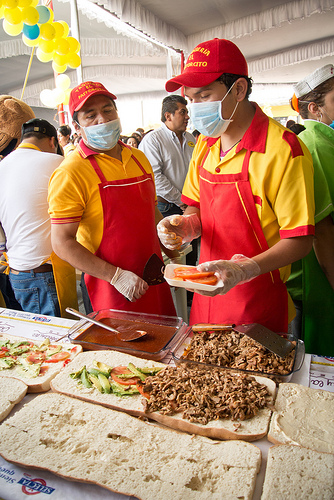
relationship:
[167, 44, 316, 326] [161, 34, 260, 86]
man wearing hat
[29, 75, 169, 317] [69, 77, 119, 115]
man wearing hat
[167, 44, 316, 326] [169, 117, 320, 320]
man wearing shirt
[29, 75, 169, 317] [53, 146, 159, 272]
man wearing shirt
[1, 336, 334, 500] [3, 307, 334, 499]
bread on table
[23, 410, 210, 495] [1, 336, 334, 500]
guacamole on bread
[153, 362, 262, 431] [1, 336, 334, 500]
meat on bread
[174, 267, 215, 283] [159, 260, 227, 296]
tomatoes in a tray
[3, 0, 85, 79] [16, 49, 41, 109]
balloons on a stick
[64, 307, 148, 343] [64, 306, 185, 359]
spoon in baking dish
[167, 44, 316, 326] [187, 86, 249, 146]
man wearing mask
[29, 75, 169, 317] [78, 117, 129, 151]
man wearing mask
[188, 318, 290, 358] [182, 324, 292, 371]
spatula on top of meat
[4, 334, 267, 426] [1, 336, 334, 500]
food on bread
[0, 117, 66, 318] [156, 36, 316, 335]
person behind man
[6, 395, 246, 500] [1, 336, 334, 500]
slice of bread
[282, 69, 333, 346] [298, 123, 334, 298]
woman in shirt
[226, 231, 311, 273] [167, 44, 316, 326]
arm of man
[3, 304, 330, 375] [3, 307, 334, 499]
edge of table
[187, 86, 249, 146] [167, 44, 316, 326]
face of man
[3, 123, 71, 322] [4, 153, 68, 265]
back of person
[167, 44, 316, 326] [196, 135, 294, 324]
man wearing apron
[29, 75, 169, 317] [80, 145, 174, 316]
man wearing apron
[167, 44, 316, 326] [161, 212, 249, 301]
man wearing gloves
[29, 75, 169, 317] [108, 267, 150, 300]
man wearing gloves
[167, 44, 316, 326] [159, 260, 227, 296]
man holding tray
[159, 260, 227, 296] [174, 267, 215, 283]
tray of tomatoes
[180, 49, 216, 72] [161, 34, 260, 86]
lettering on hat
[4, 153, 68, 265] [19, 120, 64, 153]
person wearing hat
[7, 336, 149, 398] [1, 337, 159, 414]
vegetables on slices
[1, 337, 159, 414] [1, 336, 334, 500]
slices of bread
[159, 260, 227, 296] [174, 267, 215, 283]
tray with tomatoes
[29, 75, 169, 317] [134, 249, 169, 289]
man holding spatula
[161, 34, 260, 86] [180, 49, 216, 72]
hat with lettering